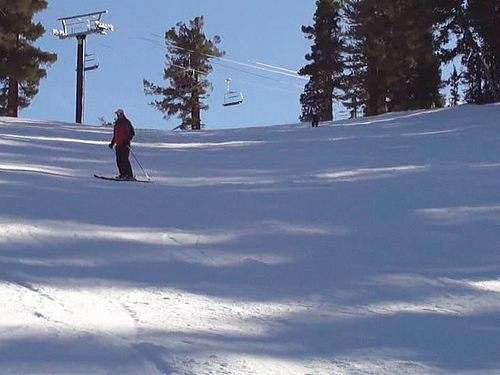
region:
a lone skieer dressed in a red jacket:
[78, 100, 160, 205]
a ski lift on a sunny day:
[203, 45, 278, 125]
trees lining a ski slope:
[307, 4, 498, 126]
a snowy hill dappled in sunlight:
[10, 186, 188, 371]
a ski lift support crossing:
[53, 11, 308, 118]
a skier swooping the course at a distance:
[294, 88, 364, 140]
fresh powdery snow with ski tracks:
[95, 263, 420, 365]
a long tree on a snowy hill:
[150, 3, 225, 158]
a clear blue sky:
[226, 6, 301, 53]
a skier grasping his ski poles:
[92, 108, 158, 186]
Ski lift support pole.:
[41, 4, 132, 133]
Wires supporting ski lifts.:
[143, 41, 308, 87]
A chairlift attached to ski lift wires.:
[208, 79, 257, 114]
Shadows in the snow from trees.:
[246, 123, 461, 313]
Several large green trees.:
[300, 6, 455, 120]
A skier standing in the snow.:
[74, 98, 177, 197]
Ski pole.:
[120, 137, 161, 186]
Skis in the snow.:
[71, 165, 164, 191]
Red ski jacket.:
[101, 121, 146, 154]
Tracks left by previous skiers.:
[13, 270, 179, 372]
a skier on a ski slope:
[300, 99, 326, 134]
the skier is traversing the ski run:
[70, 105, 360, 216]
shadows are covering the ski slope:
[5, 115, 495, 370]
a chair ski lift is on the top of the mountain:
[7, 10, 352, 135]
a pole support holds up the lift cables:
[46, 6, 111, 121]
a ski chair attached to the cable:
[216, 65, 241, 110]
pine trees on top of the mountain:
[5, 0, 495, 132]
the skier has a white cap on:
[90, 105, 150, 185]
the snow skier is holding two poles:
[86, 107, 157, 187]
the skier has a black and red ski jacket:
[92, 110, 142, 153]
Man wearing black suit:
[85, 94, 157, 192]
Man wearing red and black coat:
[75, 98, 176, 190]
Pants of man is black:
[97, 97, 157, 195]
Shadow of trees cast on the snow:
[7, 178, 448, 373]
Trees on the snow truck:
[280, 0, 490, 130]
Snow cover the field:
[6, 120, 496, 362]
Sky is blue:
[55, 7, 302, 125]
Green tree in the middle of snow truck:
[134, 10, 231, 137]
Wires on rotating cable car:
[46, 10, 311, 85]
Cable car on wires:
[210, 65, 246, 115]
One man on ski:
[91, 100, 155, 192]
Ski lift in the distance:
[211, 68, 251, 113]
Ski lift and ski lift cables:
[214, 59, 291, 113]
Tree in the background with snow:
[143, 13, 225, 133]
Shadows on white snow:
[39, 191, 484, 372]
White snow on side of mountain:
[58, 287, 163, 325]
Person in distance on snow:
[297, 96, 330, 142]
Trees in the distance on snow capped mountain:
[295, 1, 490, 97]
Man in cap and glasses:
[106, 103, 128, 125]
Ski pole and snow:
[116, 141, 167, 194]